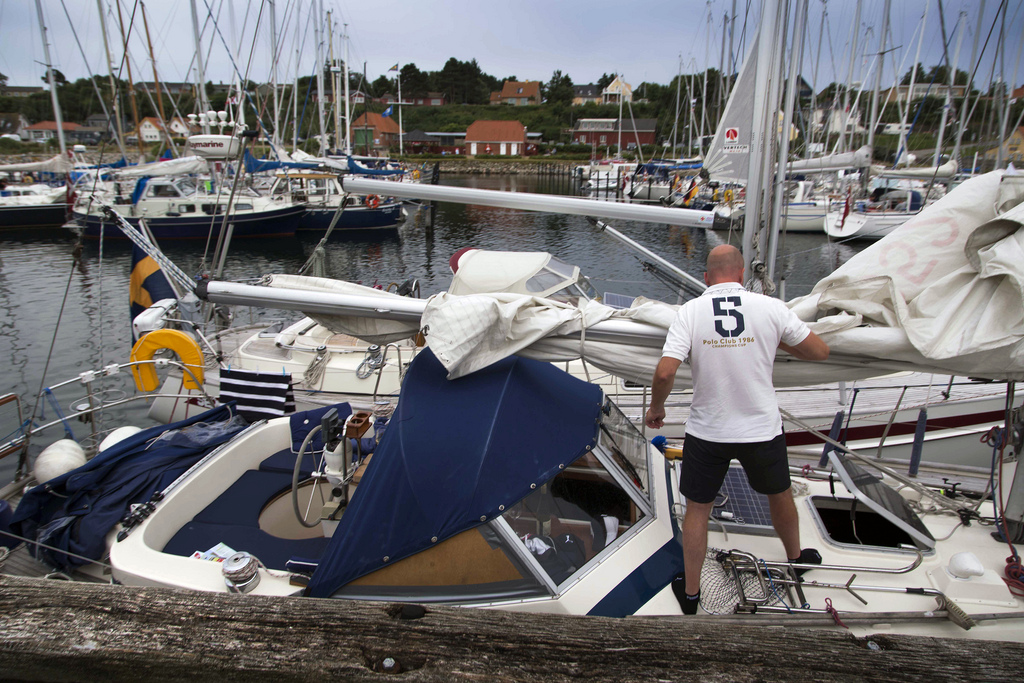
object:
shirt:
[660, 281, 813, 445]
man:
[643, 243, 832, 618]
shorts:
[676, 429, 793, 505]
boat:
[60, 174, 309, 250]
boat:
[0, 355, 1024, 683]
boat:
[217, 172, 408, 231]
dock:
[2, 0, 1024, 683]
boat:
[822, 196, 926, 239]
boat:
[707, 197, 873, 232]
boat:
[574, 163, 671, 201]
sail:
[785, 166, 1024, 363]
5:
[711, 295, 745, 338]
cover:
[304, 342, 604, 598]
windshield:
[303, 346, 660, 607]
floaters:
[127, 324, 210, 393]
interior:
[0, 389, 401, 591]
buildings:
[22, 120, 93, 145]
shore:
[0, 60, 1024, 175]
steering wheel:
[290, 424, 340, 529]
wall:
[0, 572, 1024, 679]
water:
[0, 168, 888, 474]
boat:
[0, 181, 69, 209]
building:
[464, 119, 528, 155]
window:
[470, 142, 477, 155]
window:
[517, 144, 521, 155]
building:
[349, 111, 408, 157]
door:
[352, 127, 373, 155]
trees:
[437, 55, 463, 90]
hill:
[0, 56, 1020, 148]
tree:
[393, 59, 429, 101]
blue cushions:
[161, 435, 374, 577]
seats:
[225, 502, 248, 509]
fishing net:
[699, 546, 789, 617]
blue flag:
[127, 248, 180, 349]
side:
[0, 575, 1024, 678]